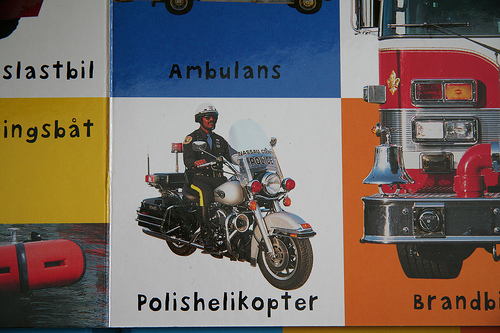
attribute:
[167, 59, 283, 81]
ambulans — word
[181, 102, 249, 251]
police — police officer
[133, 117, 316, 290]
motorcycle — black, white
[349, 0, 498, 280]
fire truck — part, red, white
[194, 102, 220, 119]
helmet — white, black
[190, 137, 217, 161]
rearview mirror — the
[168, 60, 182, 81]
letter — black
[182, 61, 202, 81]
letter — black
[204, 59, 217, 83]
letter — black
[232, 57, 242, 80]
letter — black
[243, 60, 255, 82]
letter — black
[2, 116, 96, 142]
writing — black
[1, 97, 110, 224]
square — yellow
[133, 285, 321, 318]
writing — black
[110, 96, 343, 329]
square — white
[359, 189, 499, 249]
bumper — chrome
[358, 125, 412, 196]
bell — chrome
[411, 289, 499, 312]
writing — black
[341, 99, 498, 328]
square — orange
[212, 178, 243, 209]
gas tank — white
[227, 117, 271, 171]
windshield — clear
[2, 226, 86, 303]
sea tube — red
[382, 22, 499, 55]
window wiper — black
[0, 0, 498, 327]
squares — checkered, colored